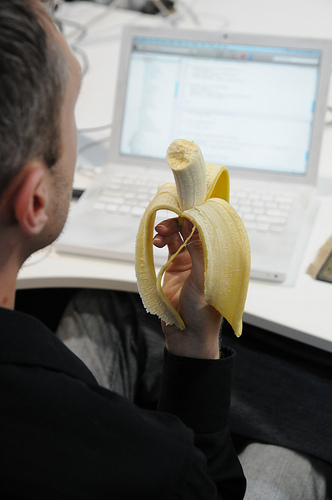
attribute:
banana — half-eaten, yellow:
[128, 133, 251, 340]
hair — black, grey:
[0, 5, 60, 176]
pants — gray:
[45, 280, 331, 496]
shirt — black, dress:
[1, 306, 246, 498]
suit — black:
[25, 328, 224, 495]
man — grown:
[0, 42, 268, 495]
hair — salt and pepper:
[2, 0, 66, 187]